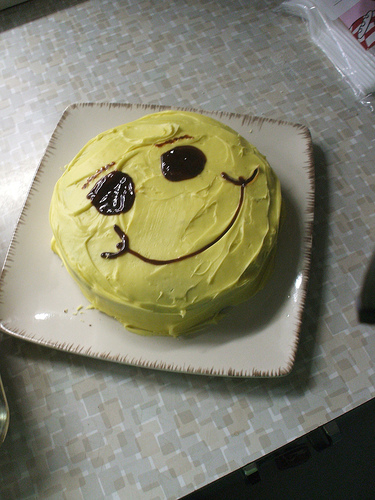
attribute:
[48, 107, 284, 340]
frosting — yellow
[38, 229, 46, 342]
plate — white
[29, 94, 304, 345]
cake — round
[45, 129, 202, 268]
cake — in the picture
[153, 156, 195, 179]
black icing — in the picture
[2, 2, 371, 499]
table — in the picture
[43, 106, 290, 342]
cake — in the picture, round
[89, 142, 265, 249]
cake —  yellow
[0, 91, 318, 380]
plate — white , rectangular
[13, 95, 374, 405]
cake — smiley face